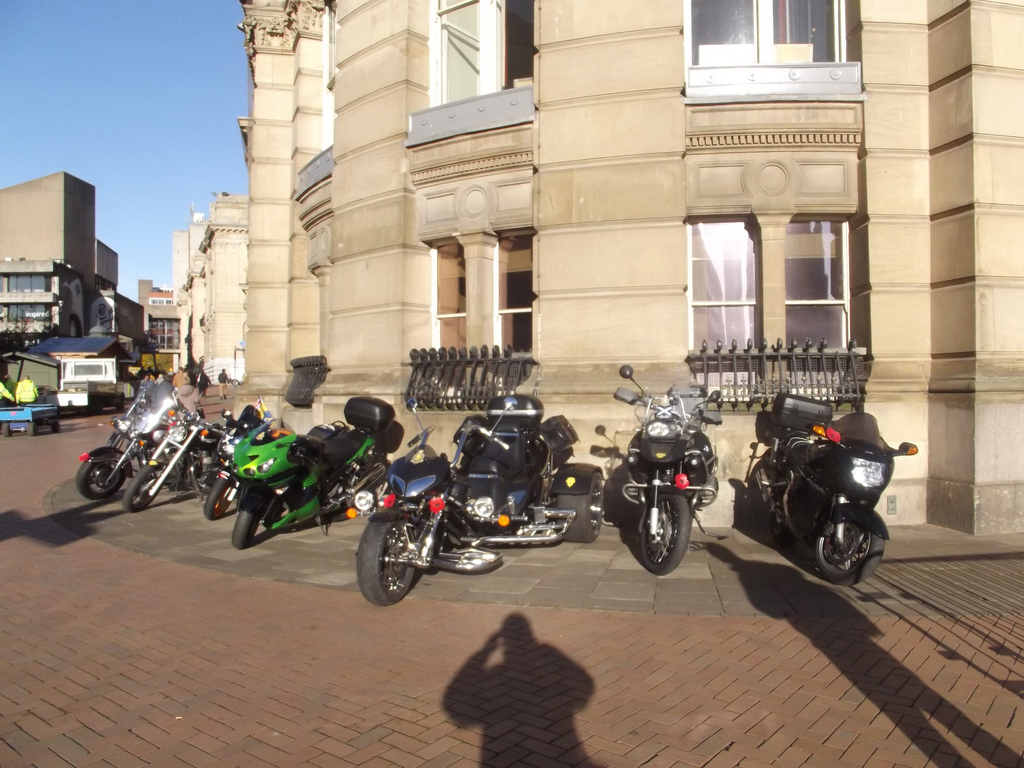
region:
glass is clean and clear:
[500, 235, 529, 308]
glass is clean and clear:
[503, 318, 532, 354]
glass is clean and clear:
[434, 318, 466, 347]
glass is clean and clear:
[437, 3, 476, 105]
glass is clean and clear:
[693, 3, 755, 68]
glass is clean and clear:
[842, 0, 861, 65]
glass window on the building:
[785, 213, 844, 300]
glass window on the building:
[691, 1, 758, 68]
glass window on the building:
[441, 2, 477, 86]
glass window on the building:
[430, 242, 463, 313]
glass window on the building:
[495, 235, 528, 308]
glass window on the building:
[491, 309, 529, 349]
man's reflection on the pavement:
[410, 582, 626, 735]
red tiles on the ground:
[106, 626, 353, 751]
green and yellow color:
[210, 432, 296, 489]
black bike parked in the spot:
[593, 359, 730, 601]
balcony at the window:
[368, 56, 607, 158]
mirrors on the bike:
[591, 357, 659, 427]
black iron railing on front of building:
[378, 313, 547, 399]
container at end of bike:
[332, 390, 400, 435]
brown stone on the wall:
[537, 149, 673, 230]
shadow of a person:
[412, 595, 629, 757]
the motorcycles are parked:
[57, 342, 940, 606]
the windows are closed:
[645, 171, 848, 386]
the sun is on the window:
[659, 182, 792, 328]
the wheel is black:
[323, 492, 438, 610]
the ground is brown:
[71, 585, 347, 750]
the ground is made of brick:
[106, 576, 356, 754]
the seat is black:
[285, 412, 378, 474]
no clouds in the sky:
[71, 115, 221, 278]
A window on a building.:
[783, 220, 851, 391]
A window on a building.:
[430, 241, 465, 387]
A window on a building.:
[495, 228, 535, 390]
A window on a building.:
[685, 2, 848, 98]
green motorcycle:
[222, 395, 409, 560]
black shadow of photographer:
[441, 610, 625, 759]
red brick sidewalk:
[10, 429, 1012, 766]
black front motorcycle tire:
[352, 500, 414, 611]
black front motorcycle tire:
[633, 495, 688, 588]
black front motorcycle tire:
[806, 505, 879, 582]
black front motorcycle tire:
[228, 489, 257, 553]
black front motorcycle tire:
[67, 435, 124, 508]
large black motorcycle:
[744, 354, 940, 610]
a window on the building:
[700, 201, 733, 379]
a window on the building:
[769, 6, 821, 93]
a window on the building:
[686, 6, 748, 93]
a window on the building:
[496, 249, 529, 342]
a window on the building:
[425, 235, 454, 337]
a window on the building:
[433, 8, 478, 110]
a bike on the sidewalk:
[766, 359, 883, 647]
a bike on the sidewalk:
[401, 381, 608, 629]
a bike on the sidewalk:
[772, 393, 853, 539]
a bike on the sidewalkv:
[605, 376, 724, 601]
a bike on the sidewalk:
[157, 414, 268, 522]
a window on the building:
[775, 221, 856, 373]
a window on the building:
[482, 238, 563, 398]